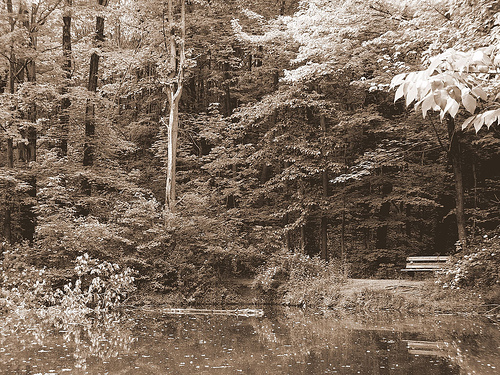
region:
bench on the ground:
[403, 251, 453, 279]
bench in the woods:
[401, 253, 448, 274]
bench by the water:
[402, 251, 454, 278]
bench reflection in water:
[408, 330, 462, 361]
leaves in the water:
[7, 255, 153, 331]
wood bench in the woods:
[399, 255, 457, 280]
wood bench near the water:
[403, 253, 451, 278]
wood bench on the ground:
[402, 253, 457, 280]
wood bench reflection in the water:
[406, 334, 462, 359]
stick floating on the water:
[161, 302, 266, 319]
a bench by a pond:
[404, 253, 454, 276]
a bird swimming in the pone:
[232, 305, 238, 315]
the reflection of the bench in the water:
[403, 337, 456, 359]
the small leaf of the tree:
[389, 70, 408, 90]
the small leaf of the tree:
[228, 147, 232, 154]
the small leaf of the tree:
[274, 173, 279, 180]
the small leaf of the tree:
[94, 262, 104, 269]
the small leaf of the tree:
[116, 215, 123, 221]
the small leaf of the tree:
[192, 198, 195, 203]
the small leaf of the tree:
[228, 182, 233, 188]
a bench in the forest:
[395, 249, 463, 279]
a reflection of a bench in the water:
[399, 329, 465, 365]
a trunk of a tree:
[159, 104, 181, 209]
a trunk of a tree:
[452, 166, 469, 251]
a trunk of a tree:
[82, 21, 106, 172]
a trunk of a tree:
[23, 112, 39, 241]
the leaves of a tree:
[407, 47, 496, 124]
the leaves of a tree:
[258, 107, 318, 176]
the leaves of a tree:
[108, 52, 141, 97]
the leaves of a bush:
[114, 217, 149, 252]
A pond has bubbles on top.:
[6, 299, 493, 374]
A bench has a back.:
[402, 253, 457, 277]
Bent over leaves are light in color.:
[388, 42, 498, 129]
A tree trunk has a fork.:
[165, 0, 184, 206]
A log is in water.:
[158, 305, 266, 318]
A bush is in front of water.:
[0, 258, 140, 368]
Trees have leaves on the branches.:
[2, 0, 497, 307]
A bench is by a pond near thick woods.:
[1, 0, 498, 372]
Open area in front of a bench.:
[349, 254, 451, 306]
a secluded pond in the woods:
[10, 299, 497, 373]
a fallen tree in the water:
[149, 303, 269, 318]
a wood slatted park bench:
[403, 253, 455, 278]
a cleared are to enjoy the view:
[295, 263, 447, 307]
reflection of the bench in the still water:
[405, 333, 473, 365]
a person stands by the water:
[219, 279, 231, 308]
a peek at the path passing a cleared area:
[213, 267, 267, 291]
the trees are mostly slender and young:
[3, 9, 493, 275]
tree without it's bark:
[158, 4, 191, 219]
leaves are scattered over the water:
[85, 309, 455, 374]